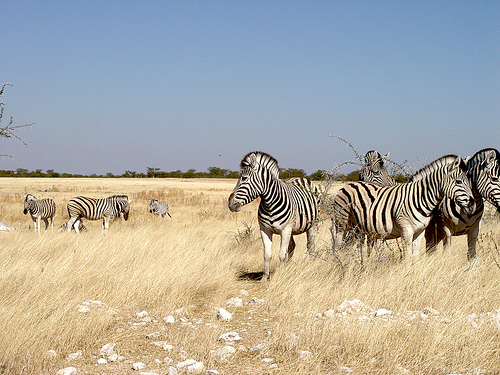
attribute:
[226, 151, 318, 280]
zebra — first, second, black, striped, large, standing, looking, facing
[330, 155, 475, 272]
zebra — second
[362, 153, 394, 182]
zebra — third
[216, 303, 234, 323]
stone — white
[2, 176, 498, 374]
grass — dry, tan, brown, tall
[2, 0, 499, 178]
sky — blue, clear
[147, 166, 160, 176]
tree — growing, green, dark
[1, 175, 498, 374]
field — grassy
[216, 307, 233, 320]
rock — large, white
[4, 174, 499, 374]
pasture — dead